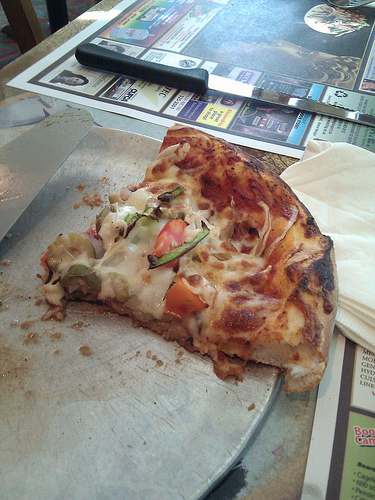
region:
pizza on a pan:
[34, 114, 341, 385]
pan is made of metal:
[49, 365, 169, 464]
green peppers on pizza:
[124, 185, 222, 288]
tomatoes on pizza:
[147, 203, 210, 335]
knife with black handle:
[62, 38, 227, 104]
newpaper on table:
[42, 69, 275, 129]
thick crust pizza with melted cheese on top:
[61, 153, 319, 359]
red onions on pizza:
[60, 216, 120, 273]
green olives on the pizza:
[38, 228, 140, 318]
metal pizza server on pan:
[0, 88, 115, 243]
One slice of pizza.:
[46, 140, 328, 333]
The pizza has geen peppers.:
[153, 218, 207, 263]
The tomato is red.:
[134, 212, 196, 265]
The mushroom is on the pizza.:
[55, 260, 117, 303]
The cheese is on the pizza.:
[60, 254, 226, 330]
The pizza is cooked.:
[175, 116, 331, 347]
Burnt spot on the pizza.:
[291, 253, 333, 286]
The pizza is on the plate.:
[0, 133, 340, 418]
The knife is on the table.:
[78, 50, 361, 149]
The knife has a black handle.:
[64, 37, 373, 158]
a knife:
[193, 62, 340, 150]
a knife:
[166, 38, 289, 148]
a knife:
[143, 34, 369, 170]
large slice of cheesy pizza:
[39, 119, 338, 393]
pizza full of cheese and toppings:
[38, 121, 338, 395]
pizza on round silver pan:
[1, 123, 283, 498]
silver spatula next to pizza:
[0, 105, 96, 238]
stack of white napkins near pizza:
[274, 138, 374, 356]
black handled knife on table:
[74, 42, 374, 123]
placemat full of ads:
[5, 2, 374, 161]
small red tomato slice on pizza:
[161, 279, 209, 321]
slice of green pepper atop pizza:
[148, 220, 208, 267]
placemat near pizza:
[299, 327, 372, 497]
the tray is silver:
[63, 314, 180, 458]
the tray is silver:
[110, 374, 249, 494]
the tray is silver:
[76, 347, 155, 484]